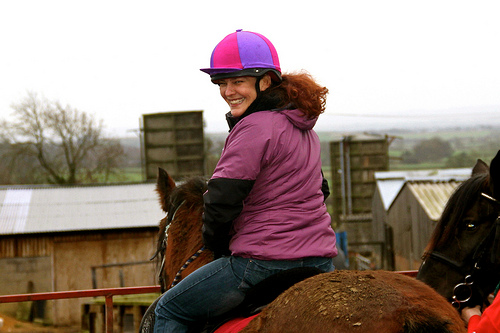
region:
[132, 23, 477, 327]
a smiling horse rider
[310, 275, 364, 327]
dirty on the horse back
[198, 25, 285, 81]
a helmet the woman is wearing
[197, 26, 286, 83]
a pink and purple helmet the woman is wearing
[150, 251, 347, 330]
jeans the woman is wearing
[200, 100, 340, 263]
a hoodie the woman is wearing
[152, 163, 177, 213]
an ear of the horse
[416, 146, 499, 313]
a part of the horse's head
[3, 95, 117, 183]
trees with no leaves in the background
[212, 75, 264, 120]
a facial expression of the lady while riding the horse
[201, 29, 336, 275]
this is a girl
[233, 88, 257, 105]
the girl is light skinned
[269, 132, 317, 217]
this is a jacket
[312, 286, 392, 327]
this is a horse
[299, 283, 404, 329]
the horse is brown in color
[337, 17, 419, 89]
this is the sky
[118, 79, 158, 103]
the sky is blue in color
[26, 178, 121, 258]
this is a building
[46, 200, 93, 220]
this is the roof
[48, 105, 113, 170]
this is a tree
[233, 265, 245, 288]
edge of a pocket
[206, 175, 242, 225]
part of an elbow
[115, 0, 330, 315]
girl sitting on brown horse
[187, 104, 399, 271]
purple t shirt on girl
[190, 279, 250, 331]
red saddle on brown horse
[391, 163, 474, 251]
angled rooftops on right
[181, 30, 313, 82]
pink and purple hat on girl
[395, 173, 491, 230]
metal roof of warehouse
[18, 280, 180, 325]
red metal rail in front of girl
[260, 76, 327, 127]
long red hair on rider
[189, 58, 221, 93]
small rim on pink hat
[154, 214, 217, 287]
harness on horse's face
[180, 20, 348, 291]
woman wearing a helmet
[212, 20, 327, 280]
woman wearing pink shirt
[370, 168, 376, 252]
large gray barn buildings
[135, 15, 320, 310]
woman wearing blue jeans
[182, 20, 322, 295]
woman sitting a horse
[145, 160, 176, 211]
ear of a horse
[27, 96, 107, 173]
tree near a barn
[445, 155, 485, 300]
horse next to rail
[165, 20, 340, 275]
woman wearing pink hat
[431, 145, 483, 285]
face of a horse